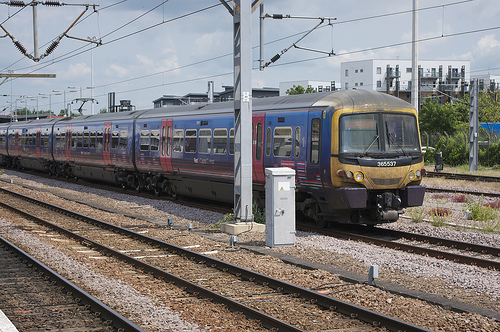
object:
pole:
[468, 78, 480, 173]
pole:
[228, 0, 254, 222]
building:
[340, 58, 473, 93]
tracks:
[0, 237, 141, 332]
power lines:
[91, 24, 330, 89]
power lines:
[101, 22, 165, 46]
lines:
[164, 0, 231, 23]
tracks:
[0, 188, 437, 332]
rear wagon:
[6, 116, 73, 172]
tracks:
[421, 187, 500, 198]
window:
[384, 111, 421, 153]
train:
[0, 85, 430, 229]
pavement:
[0, 170, 500, 308]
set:
[370, 226, 500, 268]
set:
[296, 231, 500, 301]